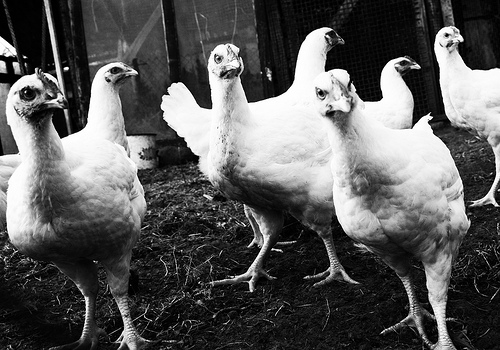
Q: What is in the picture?
A: Chickens.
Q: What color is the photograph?
A: Black and white.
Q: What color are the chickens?
A: White.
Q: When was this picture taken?
A: Daytime.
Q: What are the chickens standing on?
A: Earth.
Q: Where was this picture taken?
A: A farm.